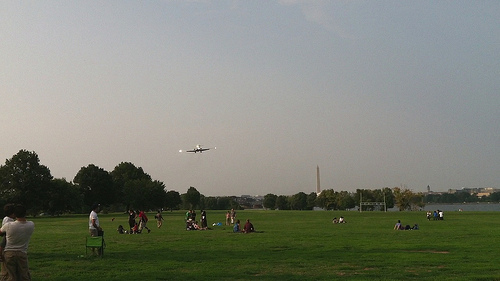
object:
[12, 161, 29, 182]
leaves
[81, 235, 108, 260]
chair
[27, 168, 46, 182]
leaves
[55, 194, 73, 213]
leaves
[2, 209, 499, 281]
grass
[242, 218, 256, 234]
people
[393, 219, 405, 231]
people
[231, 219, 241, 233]
people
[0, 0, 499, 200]
cloud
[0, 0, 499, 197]
sky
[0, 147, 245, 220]
tree